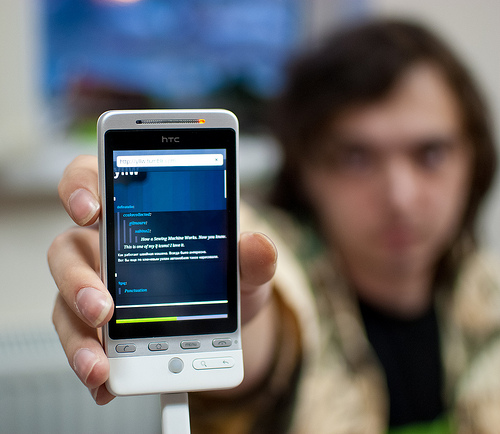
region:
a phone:
[62, 78, 350, 424]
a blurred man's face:
[298, 80, 490, 272]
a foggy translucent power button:
[161, 357, 184, 376]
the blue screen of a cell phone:
[111, 148, 229, 325]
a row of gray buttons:
[108, 335, 238, 357]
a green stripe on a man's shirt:
[386, 403, 470, 432]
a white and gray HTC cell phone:
[76, 87, 260, 424]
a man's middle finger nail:
[70, 287, 115, 327]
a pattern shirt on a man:
[282, 266, 359, 412]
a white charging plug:
[153, 392, 196, 432]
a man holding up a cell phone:
[46, 9, 489, 424]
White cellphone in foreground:
[93, 110, 242, 400]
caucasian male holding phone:
[295, 14, 498, 263]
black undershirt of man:
[352, 273, 438, 424]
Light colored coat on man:
[391, 208, 488, 425]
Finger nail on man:
[75, 285, 117, 330]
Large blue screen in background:
[40, 0, 305, 127]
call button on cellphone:
[117, 334, 140, 354]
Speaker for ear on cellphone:
[143, 115, 208, 132]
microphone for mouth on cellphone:
[168, 354, 195, 383]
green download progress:
[115, 307, 235, 326]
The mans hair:
[308, 35, 378, 97]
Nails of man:
[58, 187, 115, 220]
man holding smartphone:
[88, 100, 275, 402]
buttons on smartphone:
[111, 338, 152, 356]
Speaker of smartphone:
[127, 113, 220, 127]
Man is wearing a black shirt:
[378, 325, 438, 385]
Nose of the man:
[381, 150, 428, 217]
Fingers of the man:
[43, 160, 70, 307]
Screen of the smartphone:
[116, 164, 226, 304]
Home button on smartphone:
[163, 351, 195, 378]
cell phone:
[96, 100, 261, 390]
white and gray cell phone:
[103, 119, 236, 388]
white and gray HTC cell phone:
[111, 120, 227, 383]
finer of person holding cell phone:
[243, 231, 272, 288]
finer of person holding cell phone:
[60, 156, 99, 222]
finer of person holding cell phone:
[41, 235, 113, 310]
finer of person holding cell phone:
[49, 303, 101, 393]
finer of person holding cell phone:
[82, 385, 109, 402]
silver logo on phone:
[152, 130, 183, 146]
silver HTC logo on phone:
[156, 127, 195, 150]